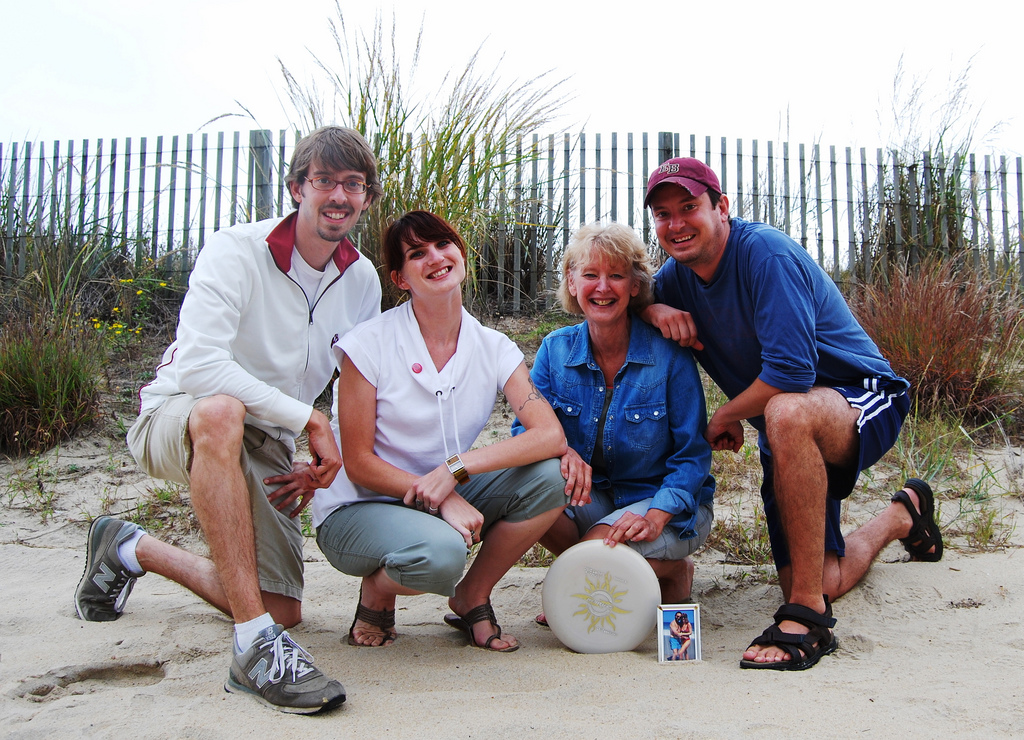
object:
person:
[510, 221, 716, 627]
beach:
[0, 361, 1024, 740]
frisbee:
[540, 538, 660, 654]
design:
[570, 566, 633, 635]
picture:
[663, 609, 696, 660]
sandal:
[892, 477, 944, 561]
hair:
[284, 125, 383, 216]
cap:
[657, 603, 703, 663]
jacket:
[139, 209, 383, 451]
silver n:
[224, 631, 345, 715]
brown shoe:
[740, 594, 838, 671]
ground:
[0, 318, 1024, 740]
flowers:
[50, 256, 167, 343]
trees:
[0, 0, 1024, 459]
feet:
[744, 595, 832, 663]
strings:
[436, 389, 460, 460]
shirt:
[312, 298, 525, 529]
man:
[643, 157, 944, 672]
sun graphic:
[570, 570, 635, 634]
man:
[74, 125, 384, 715]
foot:
[224, 611, 347, 715]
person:
[312, 211, 570, 653]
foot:
[353, 577, 399, 646]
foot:
[447, 579, 515, 648]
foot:
[892, 488, 938, 563]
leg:
[189, 394, 347, 715]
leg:
[739, 392, 830, 663]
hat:
[643, 157, 722, 209]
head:
[644, 157, 731, 265]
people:
[72, 125, 943, 715]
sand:
[0, 316, 1024, 738]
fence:
[0, 129, 1024, 319]